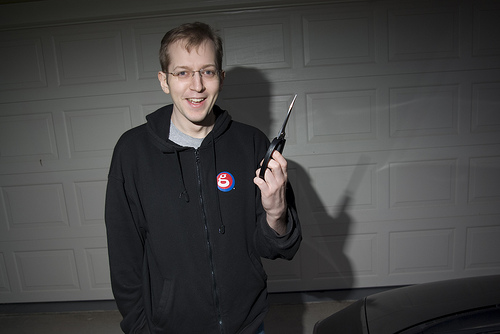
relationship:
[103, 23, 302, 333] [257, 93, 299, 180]
man holding scissors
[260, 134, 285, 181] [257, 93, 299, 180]
handle on bottom of scissors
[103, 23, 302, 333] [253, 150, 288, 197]
man has fingers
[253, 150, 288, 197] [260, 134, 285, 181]
fingers wrapped around handle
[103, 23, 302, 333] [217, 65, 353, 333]
man casting shadow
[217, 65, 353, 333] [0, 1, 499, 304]
shadow cast on garage door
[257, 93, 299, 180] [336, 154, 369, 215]
scissors casting shadow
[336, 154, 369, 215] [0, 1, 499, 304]
shadow cast on garage door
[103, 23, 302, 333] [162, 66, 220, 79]
man wearing glasses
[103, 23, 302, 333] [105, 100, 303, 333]
man wearing hoodie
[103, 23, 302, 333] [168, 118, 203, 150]
man wearing shirt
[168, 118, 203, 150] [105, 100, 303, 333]
shirt underneath hoodie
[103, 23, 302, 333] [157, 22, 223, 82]
man has hair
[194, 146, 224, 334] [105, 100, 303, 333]
zipper on front of hoodie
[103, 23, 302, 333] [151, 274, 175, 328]
man with hand in pocket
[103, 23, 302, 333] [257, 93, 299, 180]
man holding up scissors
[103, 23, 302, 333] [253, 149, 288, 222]
man has hand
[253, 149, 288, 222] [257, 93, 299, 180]
hand holding scissors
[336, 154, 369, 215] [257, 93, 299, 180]
shadow cast by scissors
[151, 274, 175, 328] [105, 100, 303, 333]
pocket on side of hoodie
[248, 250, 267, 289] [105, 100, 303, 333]
pocket on side of hoodie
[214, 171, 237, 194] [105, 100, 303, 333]
logo on front of hoodie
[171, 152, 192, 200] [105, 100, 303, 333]
drawstrings hanging from hoodie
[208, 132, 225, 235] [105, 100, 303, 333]
string hanging from hoodie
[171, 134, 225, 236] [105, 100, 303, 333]
drawstrings on front of hoodie